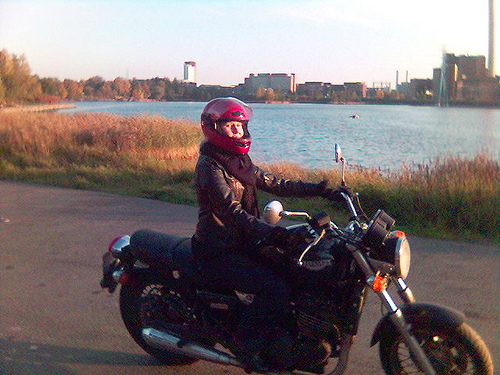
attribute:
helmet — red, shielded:
[204, 98, 251, 154]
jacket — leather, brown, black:
[193, 155, 316, 237]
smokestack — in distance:
[484, 4, 494, 69]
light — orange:
[374, 276, 387, 295]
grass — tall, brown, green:
[11, 115, 189, 191]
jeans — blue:
[213, 257, 298, 349]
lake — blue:
[57, 101, 500, 177]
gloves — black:
[262, 187, 354, 244]